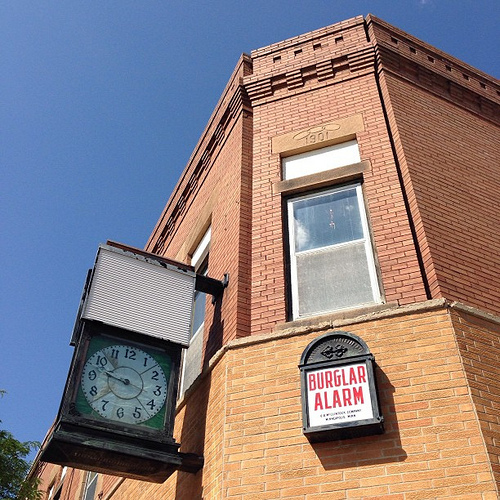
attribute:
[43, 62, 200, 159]
sky — blue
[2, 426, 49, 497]
tree limbs — green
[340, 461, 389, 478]
brick — brown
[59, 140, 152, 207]
clouds — white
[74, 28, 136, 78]
clouds — white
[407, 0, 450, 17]
clouds — white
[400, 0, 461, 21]
white clouds — white 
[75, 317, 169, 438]
clock — green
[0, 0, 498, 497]
sky — blue, cloudless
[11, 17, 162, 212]
sky — blue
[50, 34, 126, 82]
clouds — white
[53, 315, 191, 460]
clock — white, black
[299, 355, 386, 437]
sign — red , white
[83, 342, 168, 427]
clock — white, green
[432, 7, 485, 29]
sky — blue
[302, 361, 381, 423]
sign — red, white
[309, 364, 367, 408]
letters — red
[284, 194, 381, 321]
window — white, large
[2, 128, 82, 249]
clouds — white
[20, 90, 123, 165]
clouds — white 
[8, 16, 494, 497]
building — brown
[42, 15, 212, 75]
sky — blue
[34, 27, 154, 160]
sky — blue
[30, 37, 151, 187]
clouds — white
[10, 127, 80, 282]
clouds — white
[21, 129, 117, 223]
clouds — white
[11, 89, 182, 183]
sky — blue